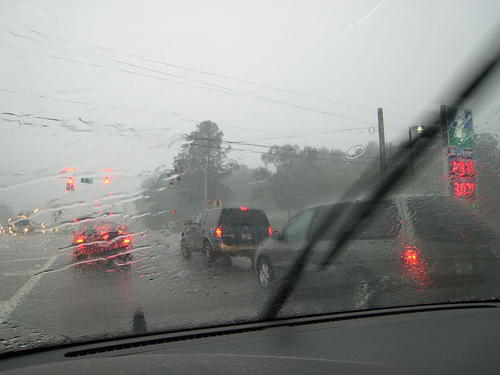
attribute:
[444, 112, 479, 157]
sign — gas station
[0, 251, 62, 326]
lines — white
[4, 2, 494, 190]
sky — blue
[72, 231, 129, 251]
lights — bright and red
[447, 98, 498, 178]
banana — yellow and green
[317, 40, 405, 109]
clouds — white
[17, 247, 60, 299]
lines — white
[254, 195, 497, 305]
suv — dark grey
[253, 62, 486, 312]
wiper — windshield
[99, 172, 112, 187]
stop light — lit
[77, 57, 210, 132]
clouds — white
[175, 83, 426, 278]
windshield — extremely wet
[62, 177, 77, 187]
traffic light — red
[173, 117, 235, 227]
tree — tall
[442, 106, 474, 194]
sign — advertising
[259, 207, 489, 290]
vehicle — gray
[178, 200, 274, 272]
vehicle — dark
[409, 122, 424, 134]
street light — illuminated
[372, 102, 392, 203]
pole — skinny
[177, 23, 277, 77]
clouds — white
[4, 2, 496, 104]
sky — blue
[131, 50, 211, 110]
clouds — white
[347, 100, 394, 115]
sky — blue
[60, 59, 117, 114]
sky — blue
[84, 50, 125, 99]
sky — blue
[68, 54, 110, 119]
clouds — white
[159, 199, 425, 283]
banana — yellow and green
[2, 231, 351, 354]
road — wet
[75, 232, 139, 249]
tail lights — on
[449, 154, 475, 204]
numbers — lit, red, bright